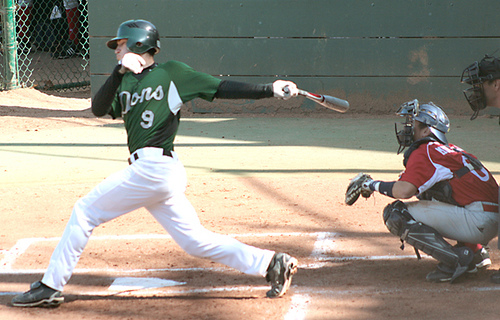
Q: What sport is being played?
A: Baseball.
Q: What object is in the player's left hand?
A: A bat.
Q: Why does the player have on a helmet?
A: For protection.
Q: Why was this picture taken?
A: Memorabilia.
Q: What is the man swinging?
A: A bat.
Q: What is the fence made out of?
A: Metal.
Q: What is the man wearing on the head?
A: A helmet.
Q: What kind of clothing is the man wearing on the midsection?
A: A shirt.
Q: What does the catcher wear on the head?
A: A helmet.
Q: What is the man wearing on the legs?
A: Shin protectors.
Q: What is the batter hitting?
A: A ball.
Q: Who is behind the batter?
A: A catcher.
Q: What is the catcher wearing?
A: A shirt.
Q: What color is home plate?
A: White.